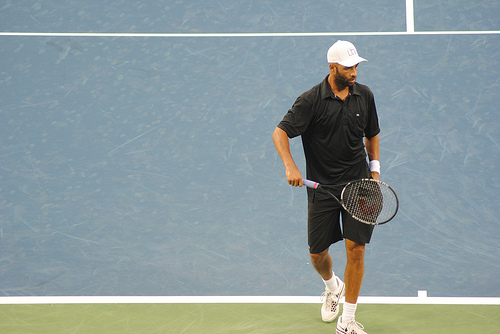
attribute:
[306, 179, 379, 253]
shorts — black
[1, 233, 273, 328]
green/blue surface — of tennis court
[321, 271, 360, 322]
white socks — in sneakers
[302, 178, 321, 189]
tennis-racket handle — purple wrapped, with red stripe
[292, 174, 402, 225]
tennis racket — black and white, with purple wrapped handle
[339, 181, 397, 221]
strings — white tennis racket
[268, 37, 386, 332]
tennis player — in black clothing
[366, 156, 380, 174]
band — white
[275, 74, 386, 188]
shirt — black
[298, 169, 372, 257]
shorts — black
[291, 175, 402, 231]
racket — tennis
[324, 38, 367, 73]
hat — white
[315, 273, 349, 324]
shoes — white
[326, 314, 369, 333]
shoes — white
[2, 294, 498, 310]
lines — white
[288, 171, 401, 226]
racquet — black, tennis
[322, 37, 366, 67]
cap — white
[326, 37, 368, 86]
head — his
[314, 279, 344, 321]
shoe — white, red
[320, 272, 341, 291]
sox — white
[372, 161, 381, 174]
wrist — white, short